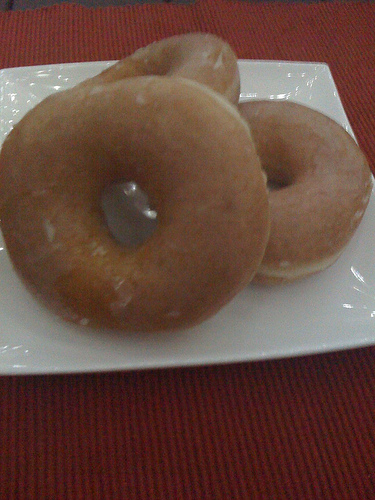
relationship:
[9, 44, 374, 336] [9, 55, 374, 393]
doughnuts on plate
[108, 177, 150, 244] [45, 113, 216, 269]
hole in middle